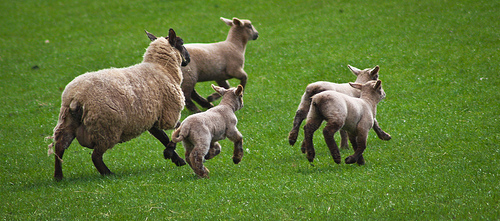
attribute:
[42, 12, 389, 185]
sheep — young , adult , face, side 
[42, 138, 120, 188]
sheep — black legs 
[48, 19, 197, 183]
sheep — wooly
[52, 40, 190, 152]
wool — tan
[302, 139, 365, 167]
hooves — black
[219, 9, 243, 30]
ears — pointed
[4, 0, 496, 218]
grass — green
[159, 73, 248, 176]
sheep — small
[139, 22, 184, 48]
ears — black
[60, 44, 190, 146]
coat — thick